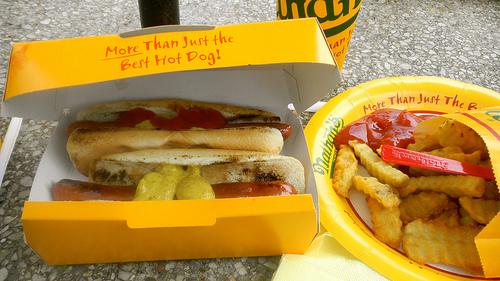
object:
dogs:
[65, 123, 292, 141]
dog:
[52, 179, 297, 201]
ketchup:
[116, 105, 228, 130]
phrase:
[104, 31, 232, 72]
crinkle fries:
[329, 119, 499, 274]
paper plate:
[301, 75, 499, 281]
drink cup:
[276, 0, 362, 78]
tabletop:
[5, 2, 493, 279]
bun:
[65, 125, 292, 177]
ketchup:
[333, 108, 423, 154]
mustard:
[132, 165, 215, 202]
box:
[0, 16, 340, 268]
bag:
[436, 105, 499, 277]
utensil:
[380, 143, 496, 180]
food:
[51, 98, 305, 202]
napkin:
[270, 232, 391, 281]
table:
[378, 6, 485, 62]